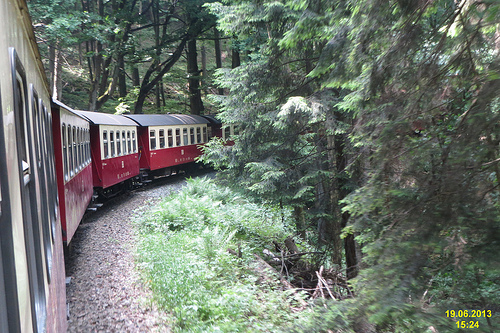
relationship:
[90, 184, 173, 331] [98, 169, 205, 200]
gravel on top of tracks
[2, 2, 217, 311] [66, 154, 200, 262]
train riding on tracks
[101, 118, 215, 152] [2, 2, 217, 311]
windows are on side of train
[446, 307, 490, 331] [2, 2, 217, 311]
lettering on side of train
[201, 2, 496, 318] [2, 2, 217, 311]
trees are beside train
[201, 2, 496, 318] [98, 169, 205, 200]
trees are behind tracks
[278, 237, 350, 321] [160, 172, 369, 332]
sticks are on grass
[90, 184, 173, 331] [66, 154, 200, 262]
gravel next to tracks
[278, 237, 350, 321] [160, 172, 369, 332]
sticks are on top of grass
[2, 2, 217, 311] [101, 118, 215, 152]
train has windows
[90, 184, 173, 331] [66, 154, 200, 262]
gravel beside tracks